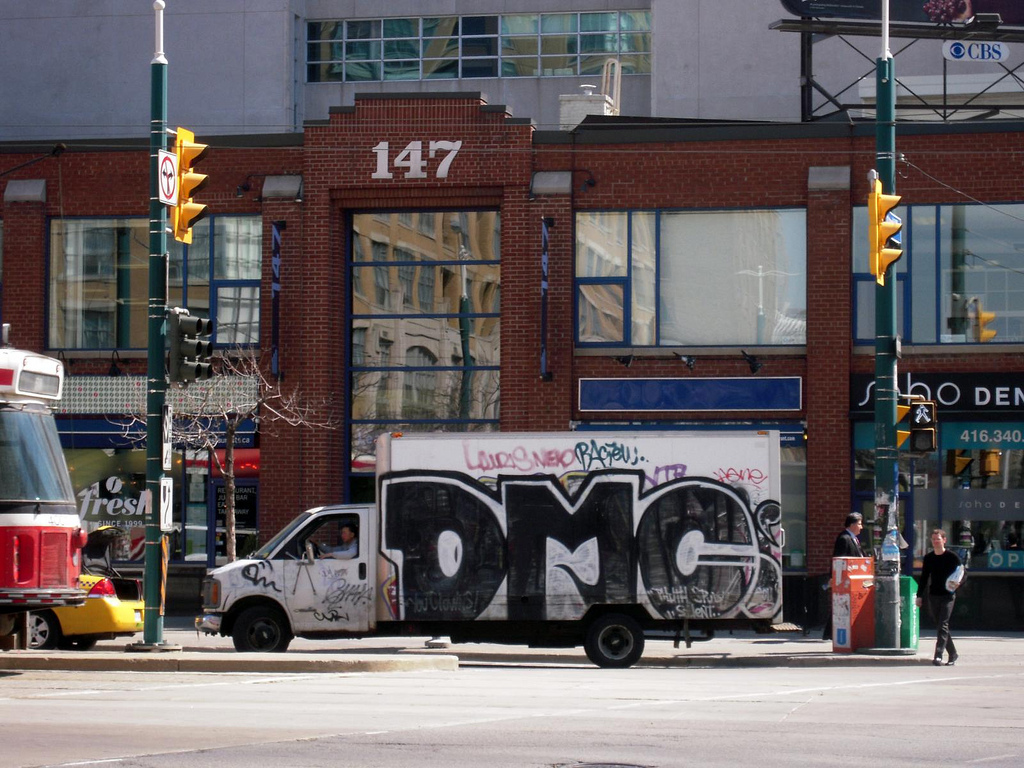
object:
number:
[366, 138, 464, 183]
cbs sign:
[937, 39, 1024, 63]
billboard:
[770, 1, 1024, 121]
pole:
[140, 0, 175, 655]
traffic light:
[169, 124, 212, 247]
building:
[0, 0, 1024, 141]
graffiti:
[378, 438, 780, 638]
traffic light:
[865, 169, 909, 286]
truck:
[191, 427, 787, 671]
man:
[914, 525, 969, 669]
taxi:
[0, 525, 149, 650]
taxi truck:
[13, 518, 148, 655]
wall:
[347, 210, 503, 472]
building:
[0, 92, 1022, 628]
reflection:
[340, 206, 504, 473]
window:
[334, 198, 507, 488]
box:
[827, 553, 878, 655]